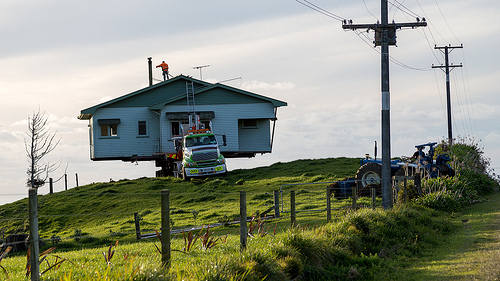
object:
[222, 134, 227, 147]
mirror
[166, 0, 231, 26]
blue sky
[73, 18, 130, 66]
sky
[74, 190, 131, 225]
grass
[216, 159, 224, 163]
right headlight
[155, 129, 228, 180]
truck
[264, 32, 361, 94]
sky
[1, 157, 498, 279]
field grass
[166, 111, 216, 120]
awnings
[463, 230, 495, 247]
ground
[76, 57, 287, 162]
house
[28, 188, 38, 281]
pole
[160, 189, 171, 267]
pole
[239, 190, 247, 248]
pole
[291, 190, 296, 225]
pole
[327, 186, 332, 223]
pole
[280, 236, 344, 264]
grass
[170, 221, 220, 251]
grass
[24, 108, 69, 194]
tree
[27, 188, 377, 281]
fence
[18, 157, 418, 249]
hills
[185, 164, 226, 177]
front fender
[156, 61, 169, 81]
man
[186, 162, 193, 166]
headlight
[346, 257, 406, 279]
weeds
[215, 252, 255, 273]
grass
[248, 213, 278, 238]
pink purse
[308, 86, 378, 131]
clouds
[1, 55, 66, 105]
sky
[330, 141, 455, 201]
tractor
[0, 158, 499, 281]
field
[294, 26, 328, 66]
cloud cover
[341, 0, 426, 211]
pole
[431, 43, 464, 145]
pole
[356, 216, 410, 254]
grass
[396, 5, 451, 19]
wires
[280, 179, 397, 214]
gate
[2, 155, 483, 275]
property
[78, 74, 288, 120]
roof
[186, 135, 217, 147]
window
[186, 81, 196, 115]
ladder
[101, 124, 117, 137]
windows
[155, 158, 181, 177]
truck bed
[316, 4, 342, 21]
wire